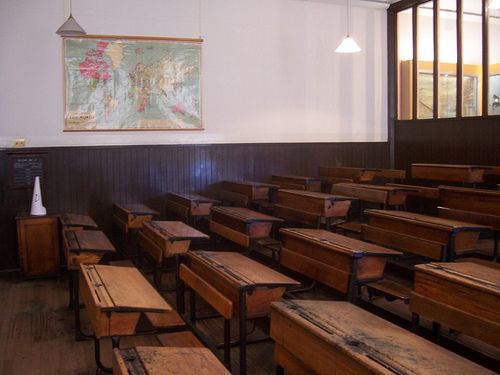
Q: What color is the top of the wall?
A: White.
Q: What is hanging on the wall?
A: World map.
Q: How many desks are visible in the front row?
A: Four.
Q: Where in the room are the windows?
A: Back.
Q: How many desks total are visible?
A: 20.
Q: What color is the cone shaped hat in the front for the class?
A: White.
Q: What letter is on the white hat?
A: D.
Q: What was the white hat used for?
A: Punishment.